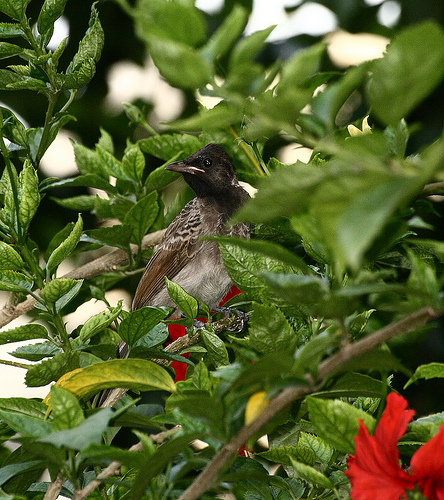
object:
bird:
[95, 141, 259, 409]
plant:
[0, 1, 443, 499]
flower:
[342, 390, 444, 498]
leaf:
[41, 355, 175, 407]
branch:
[177, 304, 436, 499]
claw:
[204, 301, 250, 336]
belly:
[152, 233, 255, 315]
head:
[162, 142, 241, 207]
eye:
[202, 157, 212, 170]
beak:
[160, 157, 206, 175]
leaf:
[364, 21, 444, 126]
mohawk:
[198, 139, 233, 162]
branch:
[43, 309, 254, 499]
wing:
[129, 196, 223, 313]